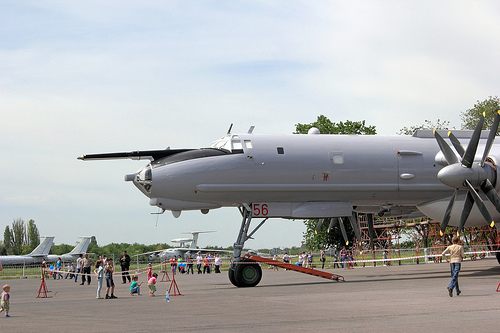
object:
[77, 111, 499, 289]
airplane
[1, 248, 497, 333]
ground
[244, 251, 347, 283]
ladder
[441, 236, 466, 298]
person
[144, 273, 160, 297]
chidren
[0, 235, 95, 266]
planes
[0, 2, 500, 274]
background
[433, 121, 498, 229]
propeller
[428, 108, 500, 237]
wings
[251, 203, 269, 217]
numbers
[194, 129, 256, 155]
cockpit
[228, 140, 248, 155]
windows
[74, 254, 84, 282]
man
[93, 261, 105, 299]
people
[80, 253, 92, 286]
people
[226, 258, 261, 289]
wheels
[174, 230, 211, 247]
tail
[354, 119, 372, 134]
antenna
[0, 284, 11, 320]
baby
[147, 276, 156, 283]
pink shirt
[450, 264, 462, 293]
jeans